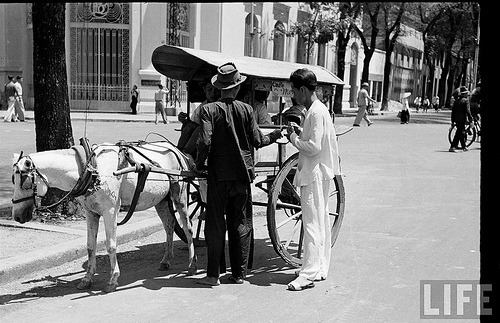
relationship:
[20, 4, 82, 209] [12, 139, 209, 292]
tree trunk next to horse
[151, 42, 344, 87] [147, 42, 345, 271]
roof on cart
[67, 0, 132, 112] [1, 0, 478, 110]
large window on building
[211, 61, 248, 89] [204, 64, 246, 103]
hat on a mans head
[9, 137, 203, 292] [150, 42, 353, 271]
white horse pulling a buggy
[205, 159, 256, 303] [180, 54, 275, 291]
pants on a man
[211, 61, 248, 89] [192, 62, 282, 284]
hat on a man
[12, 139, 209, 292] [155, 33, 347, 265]
horse pulling a carriage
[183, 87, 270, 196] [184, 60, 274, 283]
shirt on a man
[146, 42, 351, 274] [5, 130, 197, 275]
carriage connected to a horse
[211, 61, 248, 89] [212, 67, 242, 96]
hat on h head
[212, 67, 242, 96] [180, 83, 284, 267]
head of man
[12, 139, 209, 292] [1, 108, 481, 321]
horse in street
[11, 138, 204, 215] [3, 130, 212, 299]
harness on horse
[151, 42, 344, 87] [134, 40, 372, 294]
roof on carriage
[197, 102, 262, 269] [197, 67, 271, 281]
suit on man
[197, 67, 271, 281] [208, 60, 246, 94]
man with hat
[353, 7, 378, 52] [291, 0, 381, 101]
branches attached to tree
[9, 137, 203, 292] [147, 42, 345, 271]
white horse pulling cart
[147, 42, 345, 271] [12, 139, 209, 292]
cart behind horse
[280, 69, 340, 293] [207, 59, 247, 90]
man with hat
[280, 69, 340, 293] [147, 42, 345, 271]
man by cart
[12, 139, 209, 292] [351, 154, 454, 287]
horse on road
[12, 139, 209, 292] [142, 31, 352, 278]
horse pulling wagon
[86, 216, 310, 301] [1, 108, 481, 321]
shadow on street